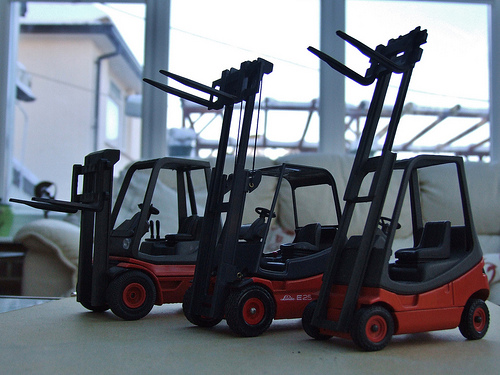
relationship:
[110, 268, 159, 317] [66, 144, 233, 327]
front wheel of lift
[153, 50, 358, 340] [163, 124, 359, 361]
front wheel of lift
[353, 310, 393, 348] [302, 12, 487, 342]
front wheel of lift